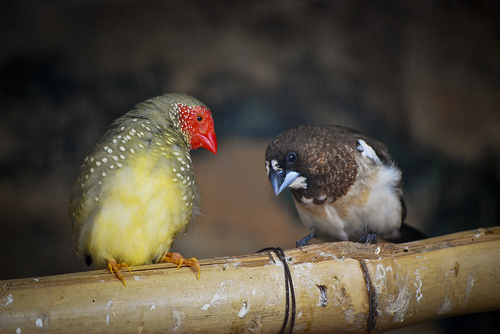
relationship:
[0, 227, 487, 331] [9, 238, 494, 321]
white spots on bamboo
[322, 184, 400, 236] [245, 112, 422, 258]
feathers on bird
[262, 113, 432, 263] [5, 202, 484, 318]
bird on log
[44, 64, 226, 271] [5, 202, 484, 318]
bird on log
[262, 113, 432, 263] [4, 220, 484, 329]
bird on bamboo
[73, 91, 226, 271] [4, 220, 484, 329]
bird on bamboo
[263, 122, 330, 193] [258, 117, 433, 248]
head on bird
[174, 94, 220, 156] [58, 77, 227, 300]
head on bird